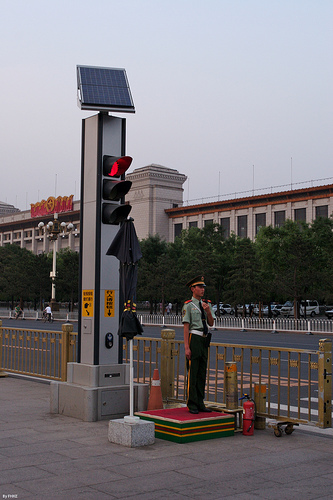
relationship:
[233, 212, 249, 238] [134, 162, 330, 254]
window on building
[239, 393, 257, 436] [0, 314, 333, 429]
fire extinguisher next to fence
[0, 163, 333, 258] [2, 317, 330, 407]
building across street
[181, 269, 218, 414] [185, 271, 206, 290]
guard wearing hat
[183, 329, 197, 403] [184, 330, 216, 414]
stripe on pants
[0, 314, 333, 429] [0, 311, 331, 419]
fence along street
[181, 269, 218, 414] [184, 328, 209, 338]
guard wearing belt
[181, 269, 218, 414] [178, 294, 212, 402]
guard wearing uniform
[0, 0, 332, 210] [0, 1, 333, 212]
clouds in sky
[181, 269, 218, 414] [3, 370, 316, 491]
guard standing at attention on sidewalk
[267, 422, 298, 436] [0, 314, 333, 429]
wheels on sliding fence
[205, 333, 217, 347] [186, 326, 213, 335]
walkie talkie radio hooked on belt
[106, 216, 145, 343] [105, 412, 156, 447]
umbrella mounted in cement block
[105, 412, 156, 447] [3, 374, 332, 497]
cement block on sidewalk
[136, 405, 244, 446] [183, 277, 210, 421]
podium for man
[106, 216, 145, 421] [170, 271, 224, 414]
umbrella for guard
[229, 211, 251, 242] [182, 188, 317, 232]
window on building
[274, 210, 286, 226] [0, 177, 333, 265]
window on building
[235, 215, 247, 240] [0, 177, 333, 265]
window on building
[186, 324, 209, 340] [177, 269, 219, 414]
belt on guard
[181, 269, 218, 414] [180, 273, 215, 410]
guard in official uniform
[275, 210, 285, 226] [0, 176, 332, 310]
window on building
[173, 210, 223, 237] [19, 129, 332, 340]
window on building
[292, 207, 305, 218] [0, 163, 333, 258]
window on building